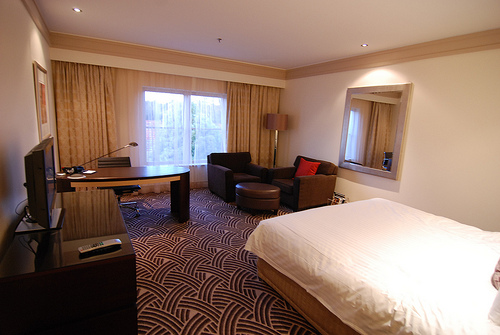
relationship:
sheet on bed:
[245, 197, 497, 331] [245, 196, 499, 333]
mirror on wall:
[321, 82, 421, 187] [254, 52, 493, 198]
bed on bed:
[244, 197, 500, 335] [245, 196, 499, 333]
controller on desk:
[77, 238, 124, 256] [2, 184, 141, 331]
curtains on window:
[53, 57, 281, 194] [142, 86, 226, 166]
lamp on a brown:
[72, 141, 136, 171] [55, 165, 191, 223]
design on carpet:
[161, 228, 230, 300] [122, 186, 321, 333]